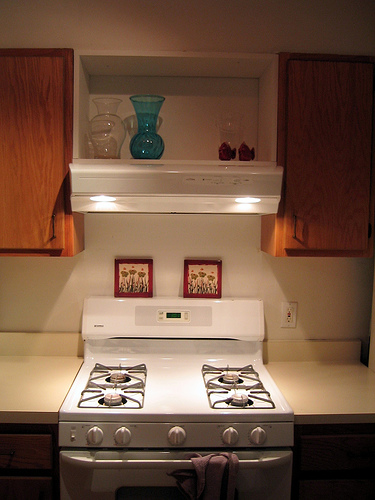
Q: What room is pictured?
A: It is a kitchen.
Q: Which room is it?
A: It is a kitchen.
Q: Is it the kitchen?
A: Yes, it is the kitchen.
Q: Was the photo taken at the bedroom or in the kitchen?
A: It was taken at the kitchen.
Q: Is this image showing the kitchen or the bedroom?
A: It is showing the kitchen.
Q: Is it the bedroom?
A: No, it is the kitchen.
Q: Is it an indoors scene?
A: Yes, it is indoors.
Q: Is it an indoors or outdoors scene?
A: It is indoors.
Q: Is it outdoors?
A: No, it is indoors.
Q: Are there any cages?
A: No, there are no cages.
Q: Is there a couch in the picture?
A: No, there are no couches.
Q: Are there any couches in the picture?
A: No, there are no couches.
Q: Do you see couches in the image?
A: No, there are no couches.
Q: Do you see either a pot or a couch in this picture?
A: No, there are no couches or pots.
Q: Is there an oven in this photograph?
A: Yes, there is an oven.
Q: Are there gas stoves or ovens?
A: Yes, there is an oven.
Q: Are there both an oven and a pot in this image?
A: No, there is an oven but no pots.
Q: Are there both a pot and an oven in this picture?
A: No, there is an oven but no pots.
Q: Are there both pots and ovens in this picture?
A: No, there is an oven but no pots.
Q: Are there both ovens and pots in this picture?
A: No, there is an oven but no pots.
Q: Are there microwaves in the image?
A: No, there are no microwaves.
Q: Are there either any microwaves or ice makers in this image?
A: No, there are no microwaves or ice makers.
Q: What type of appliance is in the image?
A: The appliance is an oven.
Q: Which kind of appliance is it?
A: The appliance is an oven.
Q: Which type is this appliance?
A: This is an oven.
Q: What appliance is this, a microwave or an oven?
A: This is an oven.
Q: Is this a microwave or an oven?
A: This is an oven.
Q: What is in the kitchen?
A: The oven is in the kitchen.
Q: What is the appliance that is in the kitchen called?
A: The appliance is an oven.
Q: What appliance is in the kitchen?
A: The appliance is an oven.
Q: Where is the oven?
A: The oven is in the kitchen.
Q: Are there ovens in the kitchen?
A: Yes, there is an oven in the kitchen.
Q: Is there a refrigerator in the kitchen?
A: No, there is an oven in the kitchen.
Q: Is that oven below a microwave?
A: No, the oven is below a picture.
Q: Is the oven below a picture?
A: Yes, the oven is below a picture.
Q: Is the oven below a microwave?
A: No, the oven is below a picture.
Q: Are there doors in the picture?
A: Yes, there is a door.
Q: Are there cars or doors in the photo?
A: Yes, there is a door.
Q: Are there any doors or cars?
A: Yes, there is a door.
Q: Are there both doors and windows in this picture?
A: No, there is a door but no windows.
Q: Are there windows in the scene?
A: No, there are no windows.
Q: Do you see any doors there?
A: Yes, there is a door.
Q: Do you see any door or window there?
A: Yes, there is a door.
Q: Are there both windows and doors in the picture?
A: No, there is a door but no windows.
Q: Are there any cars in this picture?
A: No, there are no cars.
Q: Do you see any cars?
A: No, there are no cars.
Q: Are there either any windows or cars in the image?
A: No, there are no cars or windows.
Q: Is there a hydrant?
A: No, there are no fire hydrants.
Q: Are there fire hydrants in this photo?
A: No, there are no fire hydrants.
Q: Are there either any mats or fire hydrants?
A: No, there are no fire hydrants or mats.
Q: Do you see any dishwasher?
A: No, there are no dishwashers.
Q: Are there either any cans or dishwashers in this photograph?
A: No, there are no dishwashers or cans.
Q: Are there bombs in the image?
A: No, there are no bombs.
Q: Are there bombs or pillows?
A: No, there are no bombs or pillows.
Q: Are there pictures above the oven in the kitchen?
A: Yes, there is a picture above the oven.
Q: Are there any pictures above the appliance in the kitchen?
A: Yes, there is a picture above the oven.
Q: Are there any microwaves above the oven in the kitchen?
A: No, there is a picture above the oven.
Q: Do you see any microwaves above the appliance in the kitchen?
A: No, there is a picture above the oven.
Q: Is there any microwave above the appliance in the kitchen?
A: No, there is a picture above the oven.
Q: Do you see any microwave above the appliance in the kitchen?
A: No, there is a picture above the oven.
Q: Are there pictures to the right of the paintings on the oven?
A: Yes, there is a picture to the right of the paintings.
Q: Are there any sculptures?
A: No, there are no sculptures.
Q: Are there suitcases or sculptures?
A: No, there are no sculptures or suitcases.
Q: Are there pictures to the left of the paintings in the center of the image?
A: Yes, there is a picture to the left of the paintings.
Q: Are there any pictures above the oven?
A: Yes, there is a picture above the oven.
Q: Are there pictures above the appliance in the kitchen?
A: Yes, there is a picture above the oven.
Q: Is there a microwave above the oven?
A: No, there is a picture above the oven.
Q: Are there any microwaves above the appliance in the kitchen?
A: No, there is a picture above the oven.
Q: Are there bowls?
A: No, there are no bowls.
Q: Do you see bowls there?
A: No, there are no bowls.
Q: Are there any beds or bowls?
A: No, there are no bowls or beds.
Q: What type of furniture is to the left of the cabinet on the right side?
A: The piece of furniture is a shelf.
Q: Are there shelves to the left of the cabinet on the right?
A: Yes, there is a shelf to the left of the cabinet.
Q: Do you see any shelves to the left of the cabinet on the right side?
A: Yes, there is a shelf to the left of the cabinet.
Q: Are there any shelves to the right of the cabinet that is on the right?
A: No, the shelf is to the left of the cabinet.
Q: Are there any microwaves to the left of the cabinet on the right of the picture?
A: No, there is a shelf to the left of the cabinet.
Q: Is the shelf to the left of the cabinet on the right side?
A: Yes, the shelf is to the left of the cabinet.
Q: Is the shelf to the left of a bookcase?
A: No, the shelf is to the left of the cabinet.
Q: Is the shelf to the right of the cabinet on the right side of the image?
A: No, the shelf is to the left of the cabinet.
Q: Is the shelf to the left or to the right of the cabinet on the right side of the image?
A: The shelf is to the left of the cabinet.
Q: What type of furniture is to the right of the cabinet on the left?
A: The piece of furniture is a shelf.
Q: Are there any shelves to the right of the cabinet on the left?
A: Yes, there is a shelf to the right of the cabinet.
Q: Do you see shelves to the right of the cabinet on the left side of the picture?
A: Yes, there is a shelf to the right of the cabinet.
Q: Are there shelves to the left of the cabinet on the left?
A: No, the shelf is to the right of the cabinet.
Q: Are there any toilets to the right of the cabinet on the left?
A: No, there is a shelf to the right of the cabinet.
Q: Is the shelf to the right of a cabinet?
A: Yes, the shelf is to the right of a cabinet.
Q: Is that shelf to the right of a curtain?
A: No, the shelf is to the right of a cabinet.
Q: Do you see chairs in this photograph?
A: No, there are no chairs.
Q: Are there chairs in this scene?
A: No, there are no chairs.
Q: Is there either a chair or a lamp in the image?
A: No, there are no chairs or lamps.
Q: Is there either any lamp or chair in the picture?
A: No, there are no chairs or lamps.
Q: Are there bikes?
A: No, there are no bikes.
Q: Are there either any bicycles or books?
A: No, there are no bicycles or books.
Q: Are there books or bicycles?
A: No, there are no bicycles or books.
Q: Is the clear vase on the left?
A: Yes, the vase is on the left of the image.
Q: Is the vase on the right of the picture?
A: No, the vase is on the left of the image.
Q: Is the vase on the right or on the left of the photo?
A: The vase is on the left of the image.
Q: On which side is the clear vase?
A: The vase is on the left of the image.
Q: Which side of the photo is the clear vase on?
A: The vase is on the left of the image.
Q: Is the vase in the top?
A: Yes, the vase is in the top of the image.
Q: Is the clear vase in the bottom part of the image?
A: No, the vase is in the top of the image.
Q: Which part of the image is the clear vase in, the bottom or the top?
A: The vase is in the top of the image.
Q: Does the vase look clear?
A: Yes, the vase is clear.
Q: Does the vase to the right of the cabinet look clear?
A: Yes, the vase is clear.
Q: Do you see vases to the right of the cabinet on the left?
A: Yes, there is a vase to the right of the cabinet.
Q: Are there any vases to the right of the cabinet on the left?
A: Yes, there is a vase to the right of the cabinet.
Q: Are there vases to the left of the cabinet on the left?
A: No, the vase is to the right of the cabinet.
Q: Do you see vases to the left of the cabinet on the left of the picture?
A: No, the vase is to the right of the cabinet.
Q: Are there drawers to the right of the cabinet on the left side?
A: No, there is a vase to the right of the cabinet.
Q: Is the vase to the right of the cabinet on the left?
A: Yes, the vase is to the right of the cabinet.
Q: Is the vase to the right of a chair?
A: No, the vase is to the right of the cabinet.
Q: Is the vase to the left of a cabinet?
A: No, the vase is to the right of a cabinet.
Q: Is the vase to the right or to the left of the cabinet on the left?
A: The vase is to the right of the cabinet.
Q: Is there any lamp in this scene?
A: No, there are no lamps.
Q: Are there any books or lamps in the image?
A: No, there are no lamps or books.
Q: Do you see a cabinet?
A: Yes, there is a cabinet.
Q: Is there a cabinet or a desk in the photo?
A: Yes, there is a cabinet.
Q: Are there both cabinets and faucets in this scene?
A: No, there is a cabinet but no faucets.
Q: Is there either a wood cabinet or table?
A: Yes, there is a wood cabinet.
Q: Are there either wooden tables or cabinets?
A: Yes, there is a wood cabinet.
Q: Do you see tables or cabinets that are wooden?
A: Yes, the cabinet is wooden.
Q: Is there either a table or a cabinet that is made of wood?
A: Yes, the cabinet is made of wood.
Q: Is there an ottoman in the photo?
A: No, there are no ottomen.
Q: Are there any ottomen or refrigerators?
A: No, there are no ottomen or refrigerators.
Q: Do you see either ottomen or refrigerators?
A: No, there are no ottomen or refrigerators.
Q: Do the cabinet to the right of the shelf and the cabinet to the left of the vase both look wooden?
A: Yes, both the cabinet and the cabinet are wooden.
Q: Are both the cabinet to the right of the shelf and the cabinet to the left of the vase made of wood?
A: Yes, both the cabinet and the cabinet are made of wood.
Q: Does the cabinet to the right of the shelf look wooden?
A: Yes, the cabinet is wooden.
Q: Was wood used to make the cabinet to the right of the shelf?
A: Yes, the cabinet is made of wood.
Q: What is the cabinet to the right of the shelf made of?
A: The cabinet is made of wood.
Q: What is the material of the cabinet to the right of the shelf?
A: The cabinet is made of wood.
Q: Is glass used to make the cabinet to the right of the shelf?
A: No, the cabinet is made of wood.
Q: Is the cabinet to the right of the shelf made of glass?
A: No, the cabinet is made of wood.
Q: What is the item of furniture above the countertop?
A: The piece of furniture is a cabinet.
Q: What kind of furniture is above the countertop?
A: The piece of furniture is a cabinet.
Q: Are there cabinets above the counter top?
A: Yes, there is a cabinet above the counter top.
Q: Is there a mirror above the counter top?
A: No, there is a cabinet above the counter top.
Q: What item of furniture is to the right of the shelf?
A: The piece of furniture is a cabinet.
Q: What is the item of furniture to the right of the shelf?
A: The piece of furniture is a cabinet.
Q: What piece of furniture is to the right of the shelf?
A: The piece of furniture is a cabinet.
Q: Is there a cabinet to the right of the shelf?
A: Yes, there is a cabinet to the right of the shelf.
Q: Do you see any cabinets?
A: Yes, there is a cabinet.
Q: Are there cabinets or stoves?
A: Yes, there is a cabinet.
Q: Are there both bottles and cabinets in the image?
A: No, there is a cabinet but no bottles.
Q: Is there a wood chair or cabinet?
A: Yes, there is a wood cabinet.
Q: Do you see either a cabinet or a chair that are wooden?
A: Yes, the cabinet is wooden.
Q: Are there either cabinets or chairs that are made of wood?
A: Yes, the cabinet is made of wood.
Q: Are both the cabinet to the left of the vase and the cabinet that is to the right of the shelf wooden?
A: Yes, both the cabinet and the cabinet are wooden.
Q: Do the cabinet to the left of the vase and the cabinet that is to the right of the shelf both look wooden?
A: Yes, both the cabinet and the cabinet are wooden.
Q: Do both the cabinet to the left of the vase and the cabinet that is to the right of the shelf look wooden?
A: Yes, both the cabinet and the cabinet are wooden.